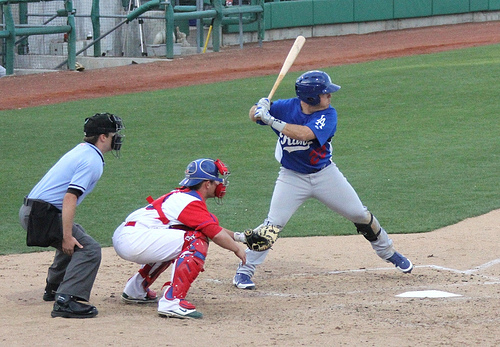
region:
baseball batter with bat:
[232, 34, 417, 292]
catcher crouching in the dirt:
[112, 154, 284, 320]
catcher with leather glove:
[111, 154, 282, 324]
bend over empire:
[19, 111, 124, 326]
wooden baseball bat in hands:
[253, 35, 305, 125]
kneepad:
[353, 205, 383, 247]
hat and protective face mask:
[79, 110, 129, 167]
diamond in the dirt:
[381, 267, 463, 315]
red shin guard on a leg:
[160, 228, 210, 320]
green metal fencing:
[1, 1, 265, 77]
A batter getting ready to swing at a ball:
[231, 34, 428, 290]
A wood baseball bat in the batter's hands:
[260, 34, 305, 119]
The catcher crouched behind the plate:
[109, 155, 280, 332]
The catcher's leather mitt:
[238, 228, 275, 255]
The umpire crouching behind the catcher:
[15, 108, 133, 320]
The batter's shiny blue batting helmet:
[288, 70, 342, 104]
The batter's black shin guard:
[349, 212, 384, 246]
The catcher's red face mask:
[208, 155, 230, 200]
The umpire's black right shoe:
[53, 292, 99, 321]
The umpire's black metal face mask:
[105, 111, 129, 154]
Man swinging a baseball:
[267, 63, 353, 258]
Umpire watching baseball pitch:
[20, 109, 127, 325]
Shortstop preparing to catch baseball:
[114, 151, 234, 318]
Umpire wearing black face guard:
[82, 108, 124, 152]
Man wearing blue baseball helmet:
[287, 67, 339, 115]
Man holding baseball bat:
[251, 33, 343, 165]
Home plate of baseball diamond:
[393, 285, 459, 303]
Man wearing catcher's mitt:
[178, 152, 279, 252]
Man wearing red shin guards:
[161, 153, 231, 314]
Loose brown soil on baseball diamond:
[256, 275, 384, 338]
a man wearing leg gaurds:
[170, 232, 208, 308]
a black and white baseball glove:
[233, 209, 281, 252]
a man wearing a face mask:
[213, 153, 232, 206]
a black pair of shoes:
[46, 277, 99, 330]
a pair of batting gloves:
[241, 75, 282, 146]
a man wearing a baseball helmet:
[289, 56, 357, 103]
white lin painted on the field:
[441, 250, 487, 284]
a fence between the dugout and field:
[6, 15, 84, 70]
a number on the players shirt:
[301, 140, 336, 171]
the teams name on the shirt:
[264, 122, 315, 169]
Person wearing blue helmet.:
[282, 60, 337, 102]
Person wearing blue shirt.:
[251, 114, 316, 164]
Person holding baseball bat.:
[234, 46, 301, 127]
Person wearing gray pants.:
[265, 183, 357, 236]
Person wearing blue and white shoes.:
[383, 248, 433, 298]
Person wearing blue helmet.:
[177, 130, 227, 185]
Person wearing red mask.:
[211, 153, 238, 223]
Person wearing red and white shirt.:
[135, 188, 187, 228]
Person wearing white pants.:
[118, 221, 155, 260]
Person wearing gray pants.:
[33, 256, 113, 271]